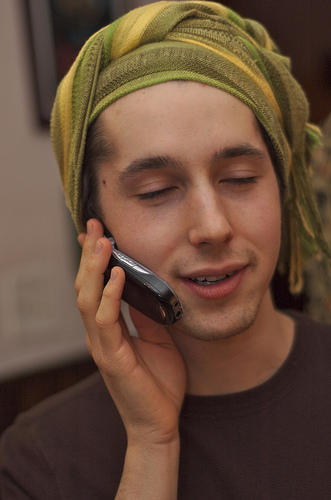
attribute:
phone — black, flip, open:
[106, 237, 184, 328]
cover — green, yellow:
[49, 0, 330, 294]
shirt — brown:
[3, 312, 330, 499]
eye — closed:
[134, 177, 184, 205]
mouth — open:
[174, 259, 255, 302]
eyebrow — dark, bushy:
[122, 154, 183, 179]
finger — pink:
[93, 267, 132, 361]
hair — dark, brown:
[79, 114, 121, 235]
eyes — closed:
[133, 163, 265, 210]